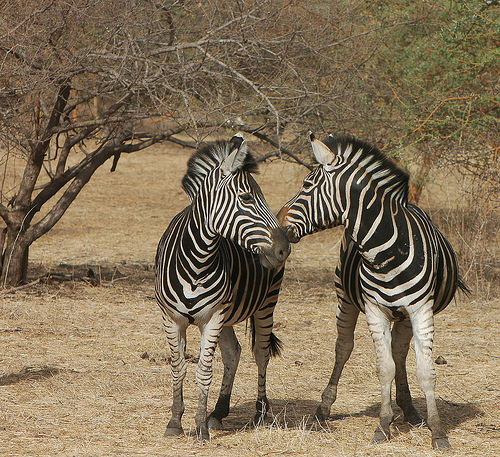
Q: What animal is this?
A: Zebra.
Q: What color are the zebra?
A: Black and white.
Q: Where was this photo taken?
A: Outside near the zebra.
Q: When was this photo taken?
A: During the day.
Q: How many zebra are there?
A: Two.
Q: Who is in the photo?
A: Just two zebra.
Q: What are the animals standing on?
A: The ground.